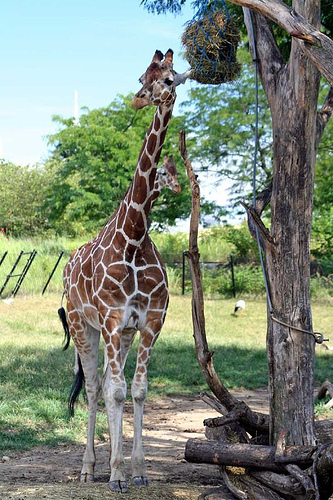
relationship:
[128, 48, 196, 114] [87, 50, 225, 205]
head of giraffe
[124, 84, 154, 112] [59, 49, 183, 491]
nose of giraffe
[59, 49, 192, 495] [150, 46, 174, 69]
giraffe has antlers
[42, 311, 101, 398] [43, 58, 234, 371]
tail on giraffe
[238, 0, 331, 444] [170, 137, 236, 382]
tree on branches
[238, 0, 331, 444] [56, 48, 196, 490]
tree on giraffe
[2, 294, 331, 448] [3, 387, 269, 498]
grass on dirty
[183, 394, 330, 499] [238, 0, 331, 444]
chopped wood on tree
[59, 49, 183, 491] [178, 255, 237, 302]
giraffe on gate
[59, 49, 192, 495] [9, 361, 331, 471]
giraffe standing in zoo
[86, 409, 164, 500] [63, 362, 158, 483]
leg of giraffe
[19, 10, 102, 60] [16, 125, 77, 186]
sky with clouds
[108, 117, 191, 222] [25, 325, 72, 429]
neck of giraffe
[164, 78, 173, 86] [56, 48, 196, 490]
eye of giraffe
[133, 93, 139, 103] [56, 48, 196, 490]
nose and mouth area of giraffe